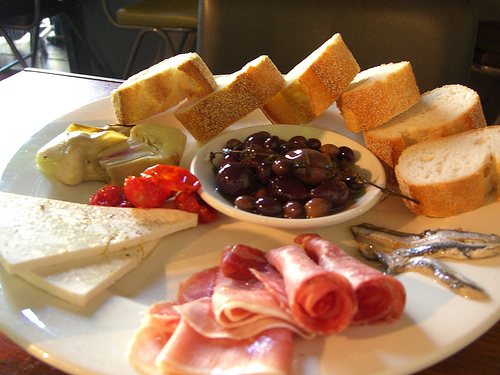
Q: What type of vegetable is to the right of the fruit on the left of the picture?
A: The vegetable is an olive.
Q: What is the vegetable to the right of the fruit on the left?
A: The vegetable is an olive.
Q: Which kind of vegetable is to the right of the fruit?
A: The vegetable is an olive.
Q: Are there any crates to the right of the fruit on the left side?
A: No, there is an olive to the right of the fruit.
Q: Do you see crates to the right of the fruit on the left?
A: No, there is an olive to the right of the fruit.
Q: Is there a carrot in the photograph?
A: No, there are no carrots.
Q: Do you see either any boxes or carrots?
A: No, there are no carrots or boxes.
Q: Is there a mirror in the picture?
A: No, there are no mirrors.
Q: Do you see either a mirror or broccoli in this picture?
A: No, there are no mirrors or broccoli.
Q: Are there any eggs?
A: No, there are no eggs.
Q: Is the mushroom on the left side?
A: Yes, the mushroom is on the left of the image.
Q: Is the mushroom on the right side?
A: No, the mushroom is on the left of the image.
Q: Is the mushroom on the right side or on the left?
A: The mushroom is on the left of the image.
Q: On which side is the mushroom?
A: The mushroom is on the left of the image.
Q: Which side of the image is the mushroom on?
A: The mushroom is on the left of the image.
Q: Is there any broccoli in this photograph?
A: No, there is no broccoli.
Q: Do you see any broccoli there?
A: No, there is no broccoli.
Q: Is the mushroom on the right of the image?
A: No, the mushroom is on the left of the image.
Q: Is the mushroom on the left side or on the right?
A: The mushroom is on the left of the image.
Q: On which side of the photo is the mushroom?
A: The mushroom is on the left of the image.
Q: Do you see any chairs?
A: Yes, there is a chair.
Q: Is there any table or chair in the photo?
A: Yes, there is a chair.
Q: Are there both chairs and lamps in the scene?
A: No, there is a chair but no lamps.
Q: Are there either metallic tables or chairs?
A: Yes, there is a metal chair.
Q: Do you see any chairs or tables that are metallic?
A: Yes, the chair is metallic.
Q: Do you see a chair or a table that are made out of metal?
A: Yes, the chair is made of metal.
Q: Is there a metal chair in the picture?
A: Yes, there is a metal chair.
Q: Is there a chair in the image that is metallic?
A: Yes, there is a chair that is metallic.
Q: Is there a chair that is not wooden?
A: Yes, there is a metallic chair.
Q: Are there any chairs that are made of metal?
A: Yes, there is a chair that is made of metal.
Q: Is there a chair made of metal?
A: Yes, there is a chair that is made of metal.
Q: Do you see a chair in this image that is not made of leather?
A: Yes, there is a chair that is made of metal.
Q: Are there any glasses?
A: No, there are no glasses.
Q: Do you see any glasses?
A: No, there are no glasses.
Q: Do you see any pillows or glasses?
A: No, there are no glasses or pillows.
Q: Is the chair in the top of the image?
A: Yes, the chair is in the top of the image.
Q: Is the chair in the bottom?
A: No, the chair is in the top of the image.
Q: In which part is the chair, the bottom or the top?
A: The chair is in the top of the image.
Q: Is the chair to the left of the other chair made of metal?
A: Yes, the chair is made of metal.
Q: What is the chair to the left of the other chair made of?
A: The chair is made of metal.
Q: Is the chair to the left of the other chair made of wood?
A: No, the chair is made of metal.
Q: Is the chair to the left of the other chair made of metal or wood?
A: The chair is made of metal.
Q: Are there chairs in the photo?
A: Yes, there is a chair.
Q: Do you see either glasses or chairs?
A: Yes, there is a chair.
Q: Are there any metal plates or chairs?
A: Yes, there is a metal chair.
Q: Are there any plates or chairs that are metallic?
A: Yes, the chair is metallic.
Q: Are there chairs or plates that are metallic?
A: Yes, the chair is metallic.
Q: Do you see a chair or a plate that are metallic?
A: Yes, the chair is metallic.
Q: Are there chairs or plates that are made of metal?
A: Yes, the chair is made of metal.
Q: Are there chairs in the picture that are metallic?
A: Yes, there is a metal chair.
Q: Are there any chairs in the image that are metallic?
A: Yes, there is a chair that is metallic.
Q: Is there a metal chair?
A: Yes, there is a chair that is made of metal.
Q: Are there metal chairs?
A: Yes, there is a chair that is made of metal.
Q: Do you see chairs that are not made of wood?
A: Yes, there is a chair that is made of metal.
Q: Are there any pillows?
A: No, there are no pillows.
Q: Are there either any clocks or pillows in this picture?
A: No, there are no pillows or clocks.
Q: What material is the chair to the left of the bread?
A: The chair is made of metal.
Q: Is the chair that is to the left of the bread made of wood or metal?
A: The chair is made of metal.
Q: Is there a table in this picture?
A: Yes, there is a table.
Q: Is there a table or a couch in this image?
A: Yes, there is a table.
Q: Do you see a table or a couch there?
A: Yes, there is a table.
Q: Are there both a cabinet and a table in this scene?
A: No, there is a table but no cabinets.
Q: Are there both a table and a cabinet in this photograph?
A: No, there is a table but no cabinets.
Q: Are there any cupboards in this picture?
A: No, there are no cupboards.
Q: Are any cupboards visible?
A: No, there are no cupboards.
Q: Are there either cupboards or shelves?
A: No, there are no cupboards or shelves.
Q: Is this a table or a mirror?
A: This is a table.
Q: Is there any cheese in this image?
A: Yes, there is cheese.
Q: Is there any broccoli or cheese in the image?
A: Yes, there is cheese.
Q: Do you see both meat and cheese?
A: Yes, there are both cheese and meat.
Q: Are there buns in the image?
A: No, there are no buns.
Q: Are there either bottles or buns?
A: No, there are no buns or bottles.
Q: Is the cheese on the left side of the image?
A: Yes, the cheese is on the left of the image.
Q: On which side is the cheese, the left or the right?
A: The cheese is on the left of the image.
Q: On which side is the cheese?
A: The cheese is on the left of the image.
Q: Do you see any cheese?
A: Yes, there is cheese.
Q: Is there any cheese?
A: Yes, there is cheese.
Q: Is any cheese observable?
A: Yes, there is cheese.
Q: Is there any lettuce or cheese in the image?
A: Yes, there is cheese.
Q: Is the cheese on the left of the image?
A: Yes, the cheese is on the left of the image.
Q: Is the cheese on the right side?
A: No, the cheese is on the left of the image.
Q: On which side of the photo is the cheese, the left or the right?
A: The cheese is on the left of the image.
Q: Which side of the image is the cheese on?
A: The cheese is on the left of the image.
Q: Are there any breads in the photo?
A: Yes, there is a bread.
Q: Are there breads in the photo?
A: Yes, there is a bread.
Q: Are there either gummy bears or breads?
A: Yes, there is a bread.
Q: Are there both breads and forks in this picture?
A: No, there is a bread but no forks.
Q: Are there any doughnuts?
A: No, there are no doughnuts.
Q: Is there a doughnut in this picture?
A: No, there are no donuts.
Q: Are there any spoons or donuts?
A: No, there are no donuts or spoons.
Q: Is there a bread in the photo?
A: Yes, there is a bread.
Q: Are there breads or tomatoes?
A: Yes, there is a bread.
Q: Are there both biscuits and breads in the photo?
A: No, there is a bread but no biscuits.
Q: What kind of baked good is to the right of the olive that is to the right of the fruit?
A: The food is a bread.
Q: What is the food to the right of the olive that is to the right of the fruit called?
A: The food is a bread.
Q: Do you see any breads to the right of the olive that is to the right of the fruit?
A: Yes, there is a bread to the right of the olive.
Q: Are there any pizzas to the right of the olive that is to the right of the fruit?
A: No, there is a bread to the right of the olive.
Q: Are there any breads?
A: Yes, there is a bread.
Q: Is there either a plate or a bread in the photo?
A: Yes, there is a bread.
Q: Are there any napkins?
A: No, there are no napkins.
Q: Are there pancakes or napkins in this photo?
A: No, there are no napkins or pancakes.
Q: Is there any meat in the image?
A: Yes, there is meat.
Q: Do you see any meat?
A: Yes, there is meat.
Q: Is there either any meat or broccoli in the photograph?
A: Yes, there is meat.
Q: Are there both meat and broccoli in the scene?
A: No, there is meat but no broccoli.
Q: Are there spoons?
A: No, there are no spoons.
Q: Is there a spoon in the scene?
A: No, there are no spoons.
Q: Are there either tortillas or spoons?
A: No, there are no spoons or tortillas.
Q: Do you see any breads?
A: Yes, there is a bread.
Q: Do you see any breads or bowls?
A: Yes, there is a bread.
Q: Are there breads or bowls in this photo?
A: Yes, there is a bread.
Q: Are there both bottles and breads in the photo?
A: No, there is a bread but no bottles.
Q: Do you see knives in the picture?
A: No, there are no knives.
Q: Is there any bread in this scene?
A: Yes, there is a bread.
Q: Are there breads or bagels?
A: Yes, there is a bread.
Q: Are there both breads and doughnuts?
A: No, there is a bread but no donuts.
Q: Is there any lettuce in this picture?
A: No, there is no lettuce.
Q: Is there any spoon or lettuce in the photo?
A: No, there are no lettuce or spoons.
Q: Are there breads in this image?
A: Yes, there is a bread.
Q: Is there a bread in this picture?
A: Yes, there is a bread.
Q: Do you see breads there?
A: Yes, there is a bread.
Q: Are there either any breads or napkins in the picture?
A: Yes, there is a bread.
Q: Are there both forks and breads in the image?
A: No, there is a bread but no forks.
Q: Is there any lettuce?
A: No, there is no lettuce.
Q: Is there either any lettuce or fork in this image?
A: No, there are no lettuce or forks.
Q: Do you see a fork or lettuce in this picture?
A: No, there are no lettuce or forks.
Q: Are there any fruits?
A: Yes, there is a fruit.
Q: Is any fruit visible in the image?
A: Yes, there is a fruit.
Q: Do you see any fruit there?
A: Yes, there is a fruit.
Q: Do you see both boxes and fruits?
A: No, there is a fruit but no boxes.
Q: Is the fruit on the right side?
A: No, the fruit is on the left of the image.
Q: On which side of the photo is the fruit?
A: The fruit is on the left of the image.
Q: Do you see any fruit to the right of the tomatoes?
A: Yes, there is a fruit to the right of the tomatoes.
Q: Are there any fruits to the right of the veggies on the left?
A: Yes, there is a fruit to the right of the tomatoes.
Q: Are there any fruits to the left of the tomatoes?
A: No, the fruit is to the right of the tomatoes.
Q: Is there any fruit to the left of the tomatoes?
A: No, the fruit is to the right of the tomatoes.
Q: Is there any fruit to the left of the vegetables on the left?
A: No, the fruit is to the right of the tomatoes.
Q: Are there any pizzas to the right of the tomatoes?
A: No, there is a fruit to the right of the tomatoes.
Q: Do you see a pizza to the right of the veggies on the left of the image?
A: No, there is a fruit to the right of the tomatoes.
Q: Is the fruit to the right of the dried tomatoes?
A: Yes, the fruit is to the right of the tomatoes.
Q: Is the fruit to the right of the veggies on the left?
A: Yes, the fruit is to the right of the tomatoes.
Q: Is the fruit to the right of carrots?
A: No, the fruit is to the right of the tomatoes.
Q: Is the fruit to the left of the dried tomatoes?
A: No, the fruit is to the right of the tomatoes.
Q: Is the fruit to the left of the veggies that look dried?
A: No, the fruit is to the right of the tomatoes.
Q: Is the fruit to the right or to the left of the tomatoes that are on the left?
A: The fruit is to the right of the tomatoes.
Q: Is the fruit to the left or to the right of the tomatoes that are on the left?
A: The fruit is to the right of the tomatoes.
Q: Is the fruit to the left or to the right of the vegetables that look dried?
A: The fruit is to the right of the tomatoes.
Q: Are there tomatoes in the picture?
A: Yes, there are tomatoes.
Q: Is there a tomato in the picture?
A: Yes, there are tomatoes.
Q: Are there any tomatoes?
A: Yes, there are tomatoes.